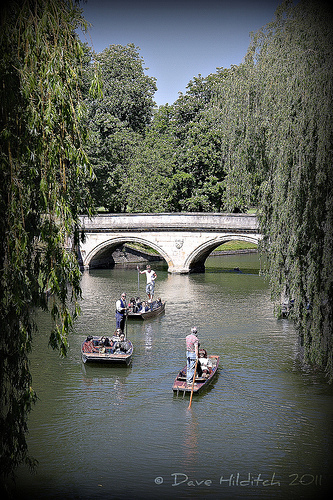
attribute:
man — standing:
[178, 322, 220, 389]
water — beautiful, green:
[59, 386, 282, 476]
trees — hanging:
[6, 112, 97, 411]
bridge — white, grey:
[76, 205, 284, 269]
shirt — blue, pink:
[176, 330, 212, 354]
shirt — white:
[104, 305, 140, 326]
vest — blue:
[115, 299, 127, 320]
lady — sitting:
[77, 332, 132, 371]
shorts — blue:
[132, 277, 161, 296]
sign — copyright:
[131, 474, 318, 491]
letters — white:
[155, 452, 313, 489]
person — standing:
[163, 321, 205, 373]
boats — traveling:
[95, 239, 258, 420]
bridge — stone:
[54, 194, 267, 267]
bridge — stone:
[29, 181, 268, 285]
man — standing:
[162, 326, 216, 402]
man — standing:
[120, 249, 192, 317]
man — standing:
[99, 292, 136, 331]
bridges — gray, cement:
[75, 192, 269, 279]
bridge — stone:
[90, 202, 268, 274]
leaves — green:
[30, 102, 66, 262]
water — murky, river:
[118, 434, 230, 460]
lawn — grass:
[226, 240, 244, 249]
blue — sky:
[135, 31, 207, 63]